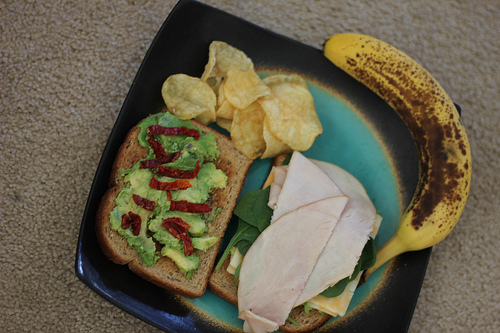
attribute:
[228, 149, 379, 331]
ham — cut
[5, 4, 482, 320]
floor — beige, carpet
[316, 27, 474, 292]
banana — yellow, very ripe, over ripened, ripped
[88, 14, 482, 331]
plate — curved, black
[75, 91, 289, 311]
sandwich — open faced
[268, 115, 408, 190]
teal — circle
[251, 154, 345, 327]
lunch meat — sliced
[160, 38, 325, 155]
potato chips — thin, crispy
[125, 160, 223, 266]
bread — wheat bread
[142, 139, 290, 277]
bread — wheat bread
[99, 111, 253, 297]
bread — sliced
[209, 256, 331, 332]
bread — sliced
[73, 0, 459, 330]
plate — black, square, dinner plate